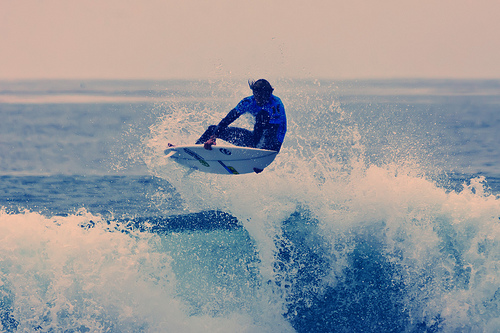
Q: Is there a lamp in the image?
A: No, there are no lamps.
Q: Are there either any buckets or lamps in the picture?
A: No, there are no lamps or buckets.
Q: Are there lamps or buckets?
A: No, there are no lamps or buckets.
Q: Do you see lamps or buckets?
A: No, there are no lamps or buckets.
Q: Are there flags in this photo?
A: No, there are no flags.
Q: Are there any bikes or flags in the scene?
A: No, there are no flags or bikes.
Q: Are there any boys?
A: No, there are no boys.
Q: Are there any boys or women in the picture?
A: No, there are no boys or women.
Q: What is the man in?
A: The man is in the air.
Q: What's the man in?
A: The man is in the air.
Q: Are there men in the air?
A: Yes, there is a man in the air.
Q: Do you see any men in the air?
A: Yes, there is a man in the air.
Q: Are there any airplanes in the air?
A: No, there is a man in the air.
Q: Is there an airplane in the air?
A: No, there is a man in the air.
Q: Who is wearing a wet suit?
A: The man is wearing a wet suit.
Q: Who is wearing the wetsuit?
A: The man is wearing a wet suit.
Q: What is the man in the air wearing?
A: The man is wearing a wetsuit.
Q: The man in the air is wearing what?
A: The man is wearing a wetsuit.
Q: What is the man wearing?
A: The man is wearing a wetsuit.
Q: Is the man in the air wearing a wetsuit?
A: Yes, the man is wearing a wetsuit.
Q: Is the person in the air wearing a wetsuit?
A: Yes, the man is wearing a wetsuit.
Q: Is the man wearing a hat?
A: No, the man is wearing a wetsuit.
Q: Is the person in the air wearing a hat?
A: No, the man is wearing a wetsuit.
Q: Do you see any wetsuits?
A: Yes, there is a wetsuit.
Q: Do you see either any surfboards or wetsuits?
A: Yes, there is a wetsuit.